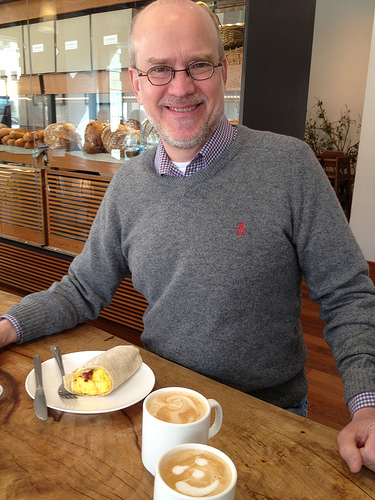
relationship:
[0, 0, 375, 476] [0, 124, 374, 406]
gentleman wearing sweater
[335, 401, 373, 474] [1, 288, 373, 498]
hand placed table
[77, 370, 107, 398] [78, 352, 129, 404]
egg inside burrito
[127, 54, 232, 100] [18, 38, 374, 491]
glasses on man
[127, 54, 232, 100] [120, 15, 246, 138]
glasses on face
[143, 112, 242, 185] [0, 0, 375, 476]
plaid collar on gentleman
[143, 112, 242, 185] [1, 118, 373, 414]
plaid collar on shirt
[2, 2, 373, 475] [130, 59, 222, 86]
gentleman wearing glasses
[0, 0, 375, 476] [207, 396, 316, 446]
gentleman standing near table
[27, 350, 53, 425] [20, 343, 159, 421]
knife on a plate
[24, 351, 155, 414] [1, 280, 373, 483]
plate on a table